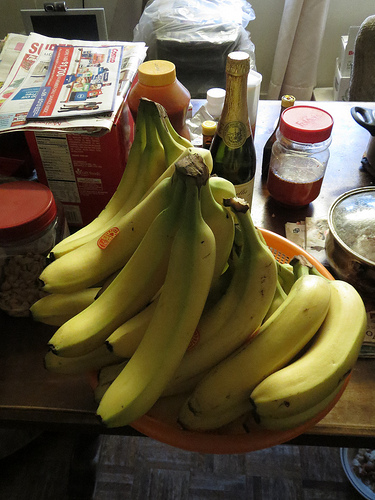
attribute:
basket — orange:
[57, 218, 366, 457]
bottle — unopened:
[208, 49, 257, 224]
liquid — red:
[264, 152, 324, 208]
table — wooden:
[3, 88, 374, 441]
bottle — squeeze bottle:
[127, 58, 189, 148]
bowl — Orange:
[140, 421, 287, 451]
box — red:
[23, 66, 123, 233]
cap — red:
[278, 103, 333, 141]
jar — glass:
[269, 127, 328, 205]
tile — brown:
[110, 435, 212, 498]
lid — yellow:
[137, 61, 175, 86]